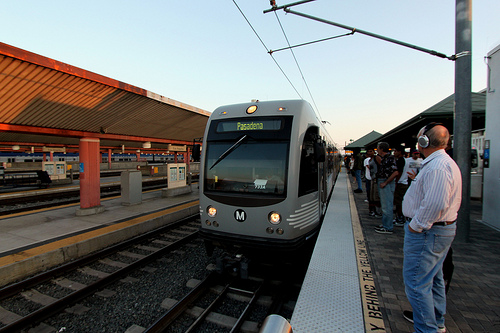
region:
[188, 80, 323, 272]
Metro train pulling into station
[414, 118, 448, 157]
Man wearing headphones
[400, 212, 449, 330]
Man wearing blue jeans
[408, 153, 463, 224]
Man wearing a white stripped shite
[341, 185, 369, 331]
Yellow caution line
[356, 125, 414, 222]
Crowd of people waiting for a train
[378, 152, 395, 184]
Man wearing a black shirt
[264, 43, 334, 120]
Electric wires over the train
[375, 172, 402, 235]
Man wearing blue jeans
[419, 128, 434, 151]
Man with balding hair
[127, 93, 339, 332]
a train on the tracks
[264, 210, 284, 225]
the headlights on a train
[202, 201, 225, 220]
headlights on a train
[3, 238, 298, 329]
brown rail ties under the tracks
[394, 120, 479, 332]
man wearing a white striped shit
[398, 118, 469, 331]
man listening to headphones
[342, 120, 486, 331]
people standing on a platform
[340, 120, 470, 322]
people waiting for a train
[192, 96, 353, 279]
train stopping at a platform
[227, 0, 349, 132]
power lines above a tram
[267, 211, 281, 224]
the light on the train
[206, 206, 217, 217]
the light on the train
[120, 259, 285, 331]
the track in front of the train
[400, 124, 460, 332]
the older heavy set man standing near the train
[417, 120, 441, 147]
the headsets on the man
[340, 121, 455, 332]
the large group of people standing near the train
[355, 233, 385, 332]
the words on the ground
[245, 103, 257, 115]
the light on the train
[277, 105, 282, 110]
the light on the train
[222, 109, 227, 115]
the light on the train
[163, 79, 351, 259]
a passenger train in train station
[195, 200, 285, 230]
front headlights of train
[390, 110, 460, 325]
man wears headphones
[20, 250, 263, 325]
gravel covers the railroad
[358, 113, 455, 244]
people in the platform of train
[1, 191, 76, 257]
yellow lines on border of platform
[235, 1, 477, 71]
a pole holding power lines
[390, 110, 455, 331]
man wears blue jeans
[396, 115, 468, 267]
man has left hand in his pocket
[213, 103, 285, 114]
three lights on top of train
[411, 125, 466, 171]
the head of a man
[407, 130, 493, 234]
a man wearing a shirt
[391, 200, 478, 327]
a man wearing blue jeans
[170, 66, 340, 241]
a train on the tracks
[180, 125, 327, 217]
the windshield on a train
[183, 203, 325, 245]
the headlights on a train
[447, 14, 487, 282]
a pole behind a man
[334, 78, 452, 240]
a lot of people at a train station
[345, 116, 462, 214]
people near a train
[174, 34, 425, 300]
a train pulling into the station